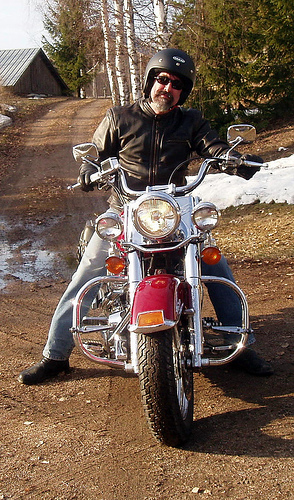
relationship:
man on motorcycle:
[19, 47, 288, 390] [43, 118, 267, 455]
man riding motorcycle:
[19, 47, 288, 390] [43, 118, 267, 455]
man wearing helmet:
[19, 47, 288, 390] [137, 42, 204, 115]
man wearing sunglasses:
[19, 47, 288, 390] [150, 73, 191, 94]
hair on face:
[150, 87, 178, 116] [152, 71, 184, 112]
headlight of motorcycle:
[129, 189, 189, 241] [43, 118, 267, 455]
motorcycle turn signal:
[43, 118, 267, 455] [194, 202, 221, 237]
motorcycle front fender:
[43, 118, 267, 455] [127, 273, 194, 333]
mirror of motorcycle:
[224, 121, 270, 148] [43, 118, 267, 455]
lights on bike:
[85, 199, 219, 245] [43, 118, 267, 455]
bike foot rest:
[43, 118, 267, 455] [211, 317, 256, 341]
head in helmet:
[145, 49, 196, 94] [137, 42, 204, 115]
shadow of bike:
[165, 299, 294, 460] [43, 118, 267, 455]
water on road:
[0, 217, 86, 289] [0, 82, 120, 319]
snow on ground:
[177, 153, 293, 213] [195, 125, 292, 267]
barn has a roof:
[2, 45, 73, 96] [2, 41, 72, 88]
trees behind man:
[42, 0, 292, 119] [19, 47, 288, 390]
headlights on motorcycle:
[85, 199, 219, 245] [43, 118, 267, 455]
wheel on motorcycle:
[130, 313, 216, 451] [43, 118, 267, 455]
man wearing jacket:
[19, 47, 288, 390] [81, 99, 242, 209]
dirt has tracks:
[2, 278, 290, 499] [2, 276, 116, 440]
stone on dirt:
[191, 484, 207, 499] [2, 278, 290, 499]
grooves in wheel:
[135, 335, 174, 444] [130, 313, 216, 451]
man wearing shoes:
[19, 47, 288, 390] [19, 351, 275, 391]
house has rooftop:
[2, 45, 73, 96] [2, 41, 72, 88]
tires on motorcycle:
[130, 313, 216, 451] [43, 118, 267, 455]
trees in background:
[42, 0, 292, 119] [1, 0, 286, 127]